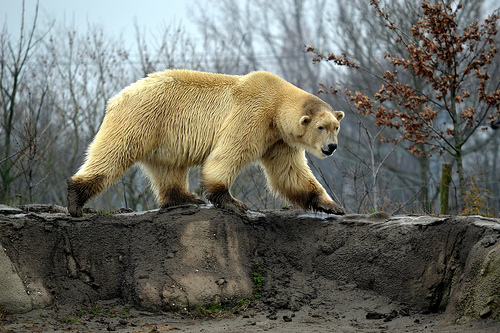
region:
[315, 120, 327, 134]
the eye of a polar bear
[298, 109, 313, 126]
the ear of a polar bear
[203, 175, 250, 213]
the paw of a polar bear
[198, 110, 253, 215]
the front leg of a polar bear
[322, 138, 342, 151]
the nose of a polar bear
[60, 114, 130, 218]
the hind leg of a polar bear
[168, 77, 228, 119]
the fur of a polar bear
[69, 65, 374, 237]
a polar bear walking on the dirt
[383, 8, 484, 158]
a tree with dried leaves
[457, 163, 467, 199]
the trunk of a tree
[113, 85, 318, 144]
the bear has white fur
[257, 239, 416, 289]
the ground is grey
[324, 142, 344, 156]
the nose is black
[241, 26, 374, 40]
trees are in the background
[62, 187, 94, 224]
the paws are muddy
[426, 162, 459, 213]
the poles are wood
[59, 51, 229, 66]
power lines are in the air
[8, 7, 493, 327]
it is a daytime photo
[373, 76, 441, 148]
the leaves are brown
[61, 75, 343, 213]
the bear is big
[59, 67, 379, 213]
bear is on the prowl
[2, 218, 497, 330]
muddy wet rock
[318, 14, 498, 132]
brown leaves on trees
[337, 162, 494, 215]
fence beside the tree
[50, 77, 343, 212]
bear looks like butterscotch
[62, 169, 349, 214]
bears feet are muddy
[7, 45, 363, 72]
power lines up in the air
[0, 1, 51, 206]
trees are bare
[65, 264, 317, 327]
grass growing in mud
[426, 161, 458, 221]
fence post is green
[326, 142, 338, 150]
Black nose on bear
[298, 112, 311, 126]
Small furry ear on bear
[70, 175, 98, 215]
Furry brown back foot on bear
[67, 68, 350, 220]
Bear with dirty white fur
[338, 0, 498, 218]
Tree with dead brown leaves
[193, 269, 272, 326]
Green plant in mud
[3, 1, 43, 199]
Thin dark tree with no leaves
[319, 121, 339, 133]
Two dark bear eyes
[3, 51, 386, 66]
Telephone wires near trees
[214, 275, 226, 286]
Small rock in dirt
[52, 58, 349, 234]
light brown bear walking across low wall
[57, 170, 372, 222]
darker brown fur near paws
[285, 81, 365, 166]
head turned to right while looking at something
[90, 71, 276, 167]
fur growing into shaggy points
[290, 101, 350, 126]
little round ears on head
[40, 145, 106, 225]
bottom of paw while walking on toe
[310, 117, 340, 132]
small round beady eyes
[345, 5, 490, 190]
short tree with brown pods along branches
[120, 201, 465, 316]
side of embankment showing mud and stones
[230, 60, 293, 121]
furry hump between head and body